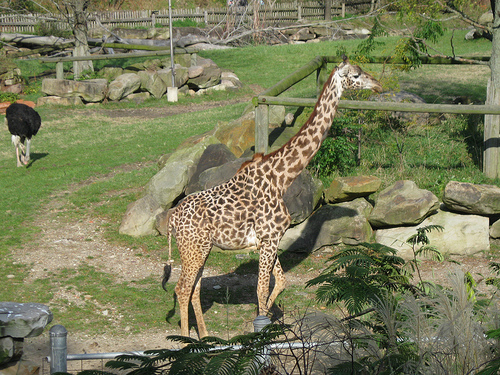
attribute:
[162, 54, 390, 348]
giraffe — walking, standing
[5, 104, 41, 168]
ostrich — standing, black, grazing, head down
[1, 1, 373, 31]
fence — wooden, brown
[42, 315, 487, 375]
fence — metal, chain linked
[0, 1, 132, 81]
tree — bare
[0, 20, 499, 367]
rocks — large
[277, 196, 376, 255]
rock — large, grey